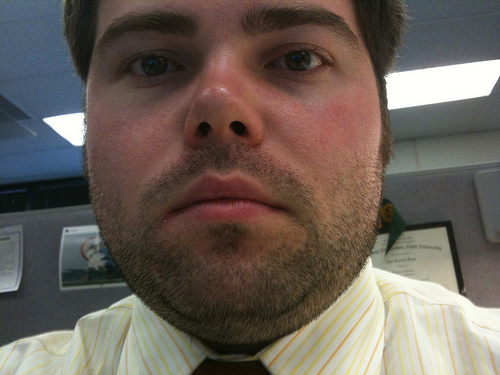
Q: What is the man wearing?
A: A striped shirt.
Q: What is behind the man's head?
A: Fluorescent lights.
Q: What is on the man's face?
A: A beard.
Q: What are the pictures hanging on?
A: A office wall.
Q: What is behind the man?
A: A dividing wall.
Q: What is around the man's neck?
A: A tie.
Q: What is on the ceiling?
A: Fluorescent lights.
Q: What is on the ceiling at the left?
A: A vent.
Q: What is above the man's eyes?
A: Eyebrows.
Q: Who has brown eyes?
A: The man.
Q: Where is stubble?
A: On man's face.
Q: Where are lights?
A: On the ceiling.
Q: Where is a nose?
A: On man's face.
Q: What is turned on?
A: Lights.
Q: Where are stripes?
A: On white shirt.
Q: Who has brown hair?
A: The man.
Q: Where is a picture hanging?
A: On the wall.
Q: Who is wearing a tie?
A: A man.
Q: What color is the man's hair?
A: Brown.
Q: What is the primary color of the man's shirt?
A: Yellow.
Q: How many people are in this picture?
A: One.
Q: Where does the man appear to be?
A: Office.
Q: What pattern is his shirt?
A: Striped.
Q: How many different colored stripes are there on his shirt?
A: Two.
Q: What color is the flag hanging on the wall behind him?
A: Green.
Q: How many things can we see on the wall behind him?
A: Four.